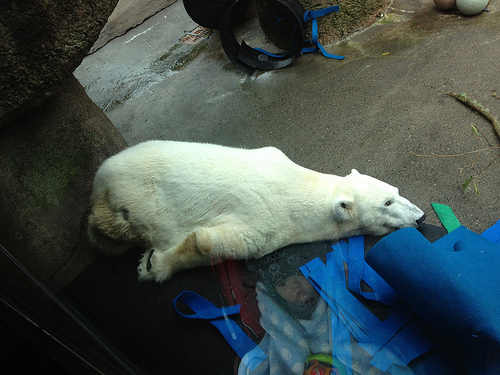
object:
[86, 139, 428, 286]
bear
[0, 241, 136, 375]
wood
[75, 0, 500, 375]
ground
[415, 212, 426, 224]
nose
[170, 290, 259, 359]
paper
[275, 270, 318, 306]
face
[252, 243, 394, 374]
child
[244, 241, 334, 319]
bandana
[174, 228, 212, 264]
spot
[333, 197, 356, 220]
ear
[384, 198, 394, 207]
eye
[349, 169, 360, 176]
ear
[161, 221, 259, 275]
leg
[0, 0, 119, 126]
wall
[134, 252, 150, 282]
claws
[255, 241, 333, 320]
reflection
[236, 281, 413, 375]
blanket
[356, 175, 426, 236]
face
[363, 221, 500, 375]
fabric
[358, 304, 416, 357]
piece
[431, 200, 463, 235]
fabric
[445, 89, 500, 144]
stick